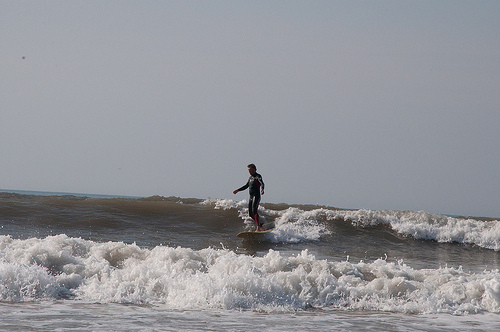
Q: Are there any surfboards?
A: Yes, there is a surfboard.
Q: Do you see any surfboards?
A: Yes, there is a surfboard.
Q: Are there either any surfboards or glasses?
A: Yes, there is a surfboard.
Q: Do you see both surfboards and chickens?
A: No, there is a surfboard but no chickens.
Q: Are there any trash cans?
A: No, there are no trash cans.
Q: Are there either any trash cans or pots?
A: No, there are no trash cans or pots.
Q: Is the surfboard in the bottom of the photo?
A: Yes, the surfboard is in the bottom of the image.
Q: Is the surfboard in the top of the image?
A: No, the surfboard is in the bottom of the image.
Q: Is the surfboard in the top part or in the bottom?
A: The surfboard is in the bottom of the image.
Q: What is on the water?
A: The surf board is on the water.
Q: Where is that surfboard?
A: The surfboard is on the water.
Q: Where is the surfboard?
A: The surfboard is on the water.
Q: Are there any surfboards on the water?
A: Yes, there is a surfboard on the water.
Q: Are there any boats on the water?
A: No, there is a surfboard on the water.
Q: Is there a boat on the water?
A: No, there is a surfboard on the water.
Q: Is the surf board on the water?
A: Yes, the surf board is on the water.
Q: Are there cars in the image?
A: No, there are no cars.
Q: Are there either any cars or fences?
A: No, there are no cars or fences.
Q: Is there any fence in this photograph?
A: No, there are no fences.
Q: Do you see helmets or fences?
A: No, there are no fences or helmets.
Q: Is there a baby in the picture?
A: No, there are no babies.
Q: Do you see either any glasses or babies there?
A: No, there are no babies or glasses.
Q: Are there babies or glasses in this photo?
A: No, there are no babies or glasses.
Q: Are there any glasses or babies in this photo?
A: No, there are no babies or glasses.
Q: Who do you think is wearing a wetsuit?
A: The man is wearing a wetsuit.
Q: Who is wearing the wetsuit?
A: The man is wearing a wetsuit.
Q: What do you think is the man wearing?
A: The man is wearing a wetsuit.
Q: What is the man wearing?
A: The man is wearing a wetsuit.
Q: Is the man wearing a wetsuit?
A: Yes, the man is wearing a wetsuit.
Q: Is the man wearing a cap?
A: No, the man is wearing a wetsuit.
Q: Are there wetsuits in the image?
A: Yes, there is a wetsuit.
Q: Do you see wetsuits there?
A: Yes, there is a wetsuit.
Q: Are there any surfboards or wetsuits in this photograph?
A: Yes, there is a wetsuit.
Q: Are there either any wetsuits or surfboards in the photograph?
A: Yes, there is a wetsuit.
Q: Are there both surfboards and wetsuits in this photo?
A: Yes, there are both a wetsuit and a surfboard.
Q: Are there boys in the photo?
A: No, there are no boys.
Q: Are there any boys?
A: No, there are no boys.